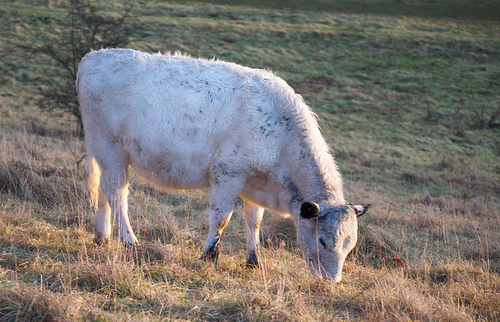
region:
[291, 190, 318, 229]
ear of the sheep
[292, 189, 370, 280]
head of the sheep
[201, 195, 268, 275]
legs of the sheep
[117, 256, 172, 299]
brown grass on the ground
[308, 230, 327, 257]
eye of the sheep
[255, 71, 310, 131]
mane of the sheep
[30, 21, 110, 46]
tree behind the sheep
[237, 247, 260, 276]
hoof of the sheep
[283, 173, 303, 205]
black marking on the sheep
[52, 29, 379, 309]
white sheep is eating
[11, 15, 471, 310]
The animal is in a pasture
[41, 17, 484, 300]
The animal is eating some grass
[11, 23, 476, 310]
The animal is watching for predators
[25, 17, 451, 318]
The animal is on a farm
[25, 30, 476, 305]
The animal is very young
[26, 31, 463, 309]
An animal is standing in the grass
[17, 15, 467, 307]
An animal is out in the sun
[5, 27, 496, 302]
An animal is enjoying the day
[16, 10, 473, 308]
The animal is very relaxed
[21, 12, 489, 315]
The animal is enjoying the peace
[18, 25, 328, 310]
picture of a sheep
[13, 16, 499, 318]
picture taken outdoors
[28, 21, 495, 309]
picture taken during the day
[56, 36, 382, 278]
a solitary cow stands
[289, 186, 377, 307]
the cow is eating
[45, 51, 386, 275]
the cow is white and furry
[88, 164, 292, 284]
the cow has short legs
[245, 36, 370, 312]
the cow's neck is down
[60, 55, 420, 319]
the cow eats grass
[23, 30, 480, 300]
picture taken outside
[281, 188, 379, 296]
Head of a cow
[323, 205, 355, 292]
Face of a bull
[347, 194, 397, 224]
Ear of a bull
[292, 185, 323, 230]
Ear of a bull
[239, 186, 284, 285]
Leg of a bull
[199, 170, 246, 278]
Leg of a bull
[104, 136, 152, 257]
Leg of a bull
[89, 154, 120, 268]
Leg of a bull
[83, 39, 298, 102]
Back of a bull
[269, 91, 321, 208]
Neck of a bull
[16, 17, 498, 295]
This photo is taken outside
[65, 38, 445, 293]
This is a cow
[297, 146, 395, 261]
The cow is grazing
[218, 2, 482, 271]
This is taken in a field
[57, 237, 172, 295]
The grass here is yellow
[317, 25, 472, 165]
The grass here is more green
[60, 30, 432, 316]
The cow is white in color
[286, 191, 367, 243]
The cow has black ears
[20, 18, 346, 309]
This is on a farm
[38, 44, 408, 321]
The cow is dirty